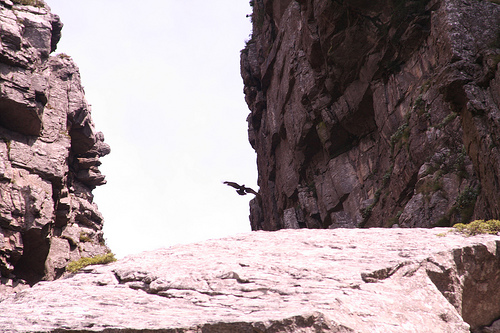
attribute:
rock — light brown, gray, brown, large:
[0, 228, 498, 331]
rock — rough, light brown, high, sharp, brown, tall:
[0, 1, 110, 289]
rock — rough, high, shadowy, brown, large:
[238, 0, 499, 231]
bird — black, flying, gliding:
[223, 181, 256, 197]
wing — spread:
[224, 181, 240, 191]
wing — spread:
[244, 187, 257, 196]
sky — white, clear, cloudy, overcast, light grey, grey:
[47, 0, 253, 257]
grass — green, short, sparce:
[455, 218, 499, 237]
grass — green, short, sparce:
[66, 251, 117, 274]